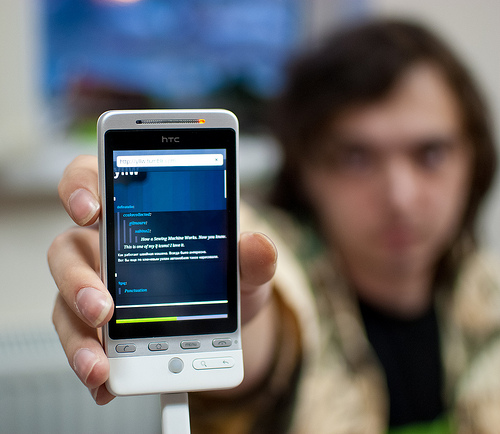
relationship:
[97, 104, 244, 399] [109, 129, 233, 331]
cell phone has screen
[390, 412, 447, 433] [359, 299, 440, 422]
stripe on shirt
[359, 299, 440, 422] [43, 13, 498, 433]
shirt on man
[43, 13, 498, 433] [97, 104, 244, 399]
man holding up cell phone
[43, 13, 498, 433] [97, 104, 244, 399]
man holding cell phone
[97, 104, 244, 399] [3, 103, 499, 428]
cell phone in foreground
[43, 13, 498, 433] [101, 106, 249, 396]
male holding phone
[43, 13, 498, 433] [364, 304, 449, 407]
man has undershirt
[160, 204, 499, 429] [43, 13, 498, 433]
coat on man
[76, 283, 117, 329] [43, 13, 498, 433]
finger nail on man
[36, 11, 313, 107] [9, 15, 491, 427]
screen in background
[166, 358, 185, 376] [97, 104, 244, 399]
call button on cell phone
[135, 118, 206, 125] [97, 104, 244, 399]
microphone on cell phone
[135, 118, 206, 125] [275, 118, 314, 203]
microphone for ear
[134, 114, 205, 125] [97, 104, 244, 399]
microphone on cell phone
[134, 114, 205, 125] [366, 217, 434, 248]
microphone for mouth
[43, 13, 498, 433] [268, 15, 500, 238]
man has hair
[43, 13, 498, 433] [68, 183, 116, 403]
man has nails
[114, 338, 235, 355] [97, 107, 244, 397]
buttons on cell phone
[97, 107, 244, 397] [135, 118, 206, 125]
cell phone has microphone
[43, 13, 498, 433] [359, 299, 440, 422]
man wearing shirt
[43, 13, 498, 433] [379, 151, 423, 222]
man has nose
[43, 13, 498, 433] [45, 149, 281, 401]
man has fingers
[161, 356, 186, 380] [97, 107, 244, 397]
home button on cell phone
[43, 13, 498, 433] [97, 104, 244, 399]
person holding cell phone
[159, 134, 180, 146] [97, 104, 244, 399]
logo on cell phone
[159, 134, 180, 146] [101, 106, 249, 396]
logo on phone